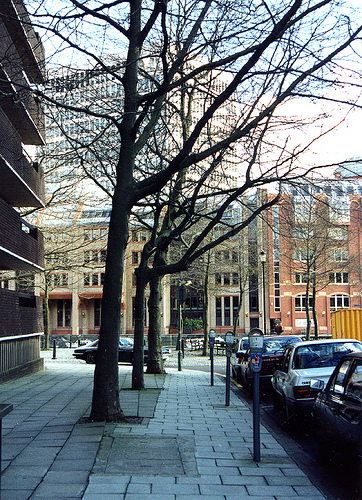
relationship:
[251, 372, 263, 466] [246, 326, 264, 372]
pole on meter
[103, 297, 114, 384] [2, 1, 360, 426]
bark on tree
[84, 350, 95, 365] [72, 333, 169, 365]
tire on car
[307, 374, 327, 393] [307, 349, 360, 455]
mirror on car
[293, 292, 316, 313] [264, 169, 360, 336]
windows on building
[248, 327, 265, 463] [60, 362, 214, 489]
meter at sidewalk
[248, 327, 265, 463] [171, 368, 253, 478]
meter at sidewalk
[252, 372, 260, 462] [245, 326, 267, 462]
pole on meter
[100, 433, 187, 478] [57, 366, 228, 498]
stone on sidewalk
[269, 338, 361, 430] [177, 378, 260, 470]
car parked by sidewalk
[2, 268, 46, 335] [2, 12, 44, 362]
porch on building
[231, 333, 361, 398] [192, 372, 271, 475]
cars parked by sidewalk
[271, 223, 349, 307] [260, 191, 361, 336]
windows on building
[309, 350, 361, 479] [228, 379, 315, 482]
car parked next to curb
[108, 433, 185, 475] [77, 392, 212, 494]
panels on sidewalk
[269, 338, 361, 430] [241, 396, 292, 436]
car parked next to curb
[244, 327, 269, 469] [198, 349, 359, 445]
meter by street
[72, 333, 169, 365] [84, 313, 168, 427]
car obscured by trees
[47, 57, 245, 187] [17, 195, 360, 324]
building overlooking city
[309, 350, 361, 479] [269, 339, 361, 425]
car behind car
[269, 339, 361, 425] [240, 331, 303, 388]
car behind car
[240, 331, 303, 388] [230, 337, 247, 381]
car behind car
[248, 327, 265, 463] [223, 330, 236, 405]
meter behind parking meter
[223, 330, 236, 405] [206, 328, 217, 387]
parking meter behind parking meter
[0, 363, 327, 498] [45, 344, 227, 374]
sidewalk near street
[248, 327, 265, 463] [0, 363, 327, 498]
meter on sidewalk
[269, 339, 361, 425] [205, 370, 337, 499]
car parked at curb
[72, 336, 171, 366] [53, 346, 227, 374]
car at street corner